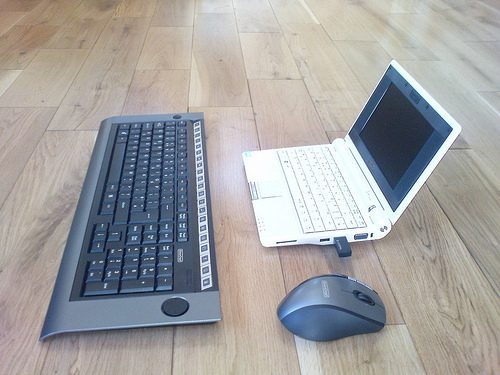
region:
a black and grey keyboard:
[35, 110, 220, 342]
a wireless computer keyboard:
[39, 110, 221, 345]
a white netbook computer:
[237, 59, 464, 265]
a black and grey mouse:
[275, 274, 386, 344]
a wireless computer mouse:
[278, 274, 389, 341]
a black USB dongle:
[332, 235, 352, 260]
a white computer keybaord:
[278, 145, 368, 230]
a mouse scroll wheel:
[355, 291, 372, 303]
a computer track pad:
[254, 175, 283, 197]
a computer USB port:
[317, 238, 330, 244]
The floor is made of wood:
[33, 1, 484, 109]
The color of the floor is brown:
[10, 5, 332, 87]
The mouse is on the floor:
[270, 269, 391, 346]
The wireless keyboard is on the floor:
[34, 98, 226, 357]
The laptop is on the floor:
[242, 54, 455, 256]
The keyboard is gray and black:
[39, 103, 217, 333]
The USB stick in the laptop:
[328, 233, 359, 264]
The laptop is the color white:
[240, 104, 372, 247]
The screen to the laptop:
[346, 71, 435, 206]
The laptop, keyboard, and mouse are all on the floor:
[28, 17, 491, 352]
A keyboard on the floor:
[107, 120, 198, 317]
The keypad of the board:
[125, 132, 167, 282]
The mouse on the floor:
[300, 285, 366, 325]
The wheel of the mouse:
[360, 295, 370, 300]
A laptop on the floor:
[262, 154, 354, 232]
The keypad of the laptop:
[307, 154, 325, 224]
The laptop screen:
[383, 112, 405, 166]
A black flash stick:
[337, 237, 347, 252]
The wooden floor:
[230, 332, 275, 373]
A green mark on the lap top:
[245, 151, 249, 156]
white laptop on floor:
[249, 60, 436, 252]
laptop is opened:
[254, 53, 460, 262]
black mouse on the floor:
[262, 255, 397, 335]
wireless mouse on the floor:
[270, 265, 399, 342]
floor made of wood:
[10, 5, 487, 352]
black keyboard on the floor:
[50, 93, 230, 339]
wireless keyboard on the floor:
[40, 97, 217, 314]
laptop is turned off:
[237, 64, 423, 244]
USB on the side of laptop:
[250, 63, 453, 261]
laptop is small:
[239, 63, 459, 246]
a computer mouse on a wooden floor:
[271, 270, 387, 342]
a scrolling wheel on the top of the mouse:
[352, 287, 369, 303]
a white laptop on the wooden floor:
[235, 50, 465, 260]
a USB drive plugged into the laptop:
[330, 230, 350, 256]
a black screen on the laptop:
[345, 61, 455, 201]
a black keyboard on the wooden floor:
[35, 105, 222, 345]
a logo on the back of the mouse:
[315, 280, 330, 300]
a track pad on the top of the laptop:
[250, 176, 280, 196]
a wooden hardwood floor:
[0, 0, 496, 372]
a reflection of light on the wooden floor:
[199, 1, 275, 22]